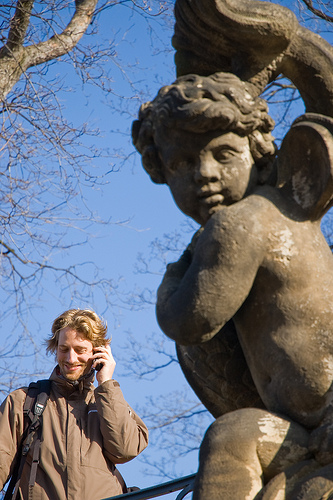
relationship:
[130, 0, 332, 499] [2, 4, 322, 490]
carving in park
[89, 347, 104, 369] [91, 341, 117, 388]
phone in hand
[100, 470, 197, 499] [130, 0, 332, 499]
rail near carving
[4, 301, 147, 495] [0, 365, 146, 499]
man in coat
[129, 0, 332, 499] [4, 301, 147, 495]
carving next to man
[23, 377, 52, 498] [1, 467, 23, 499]
strap on bag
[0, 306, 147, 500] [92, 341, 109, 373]
man on phone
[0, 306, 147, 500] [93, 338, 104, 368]
man on phone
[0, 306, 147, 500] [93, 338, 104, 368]
man smiling phone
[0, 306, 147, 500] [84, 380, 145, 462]
man in sleeves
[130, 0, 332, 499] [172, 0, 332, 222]
carving with wings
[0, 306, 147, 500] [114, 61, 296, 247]
man and statue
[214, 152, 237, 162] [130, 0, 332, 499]
eye of carving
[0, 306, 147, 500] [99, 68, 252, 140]
man has blonde hair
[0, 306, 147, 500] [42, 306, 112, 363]
man has blonde hair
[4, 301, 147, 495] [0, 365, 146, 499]
man wearing coat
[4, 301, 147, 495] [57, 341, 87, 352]
man has eyebrows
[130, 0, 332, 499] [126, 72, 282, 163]
carving has hair